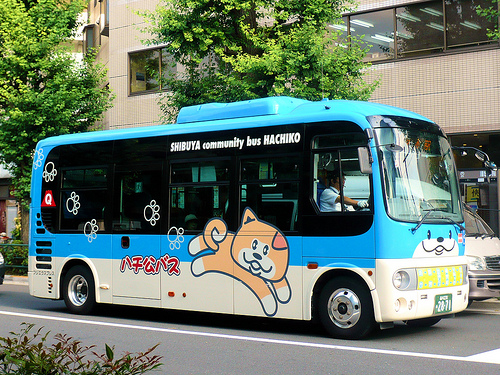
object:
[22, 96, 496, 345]
bus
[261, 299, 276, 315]
paws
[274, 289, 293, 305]
paws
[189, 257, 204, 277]
paws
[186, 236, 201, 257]
paws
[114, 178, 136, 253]
small puddles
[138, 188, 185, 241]
tracks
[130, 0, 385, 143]
plant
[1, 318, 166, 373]
plant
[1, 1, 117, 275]
plant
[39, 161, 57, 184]
paw mark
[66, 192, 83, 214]
paw mark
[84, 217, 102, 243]
paw mark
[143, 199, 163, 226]
paw mark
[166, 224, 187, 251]
paw mark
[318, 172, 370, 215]
man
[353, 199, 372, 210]
gloves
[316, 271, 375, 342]
front wheel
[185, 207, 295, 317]
animal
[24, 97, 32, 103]
green leaf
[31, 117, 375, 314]
side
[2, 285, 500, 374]
road